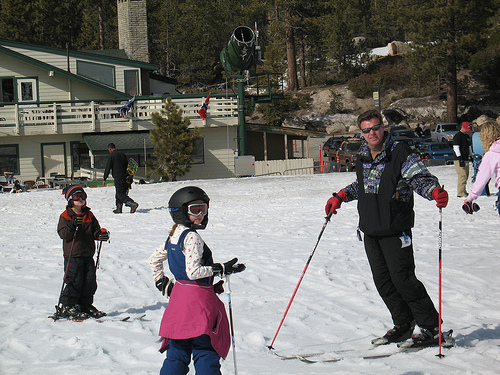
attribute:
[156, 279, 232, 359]
jacket — pink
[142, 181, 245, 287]
girl — young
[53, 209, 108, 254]
jacket — black, red, brown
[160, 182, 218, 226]
helmet — black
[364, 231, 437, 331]
pants — black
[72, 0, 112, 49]
tree — green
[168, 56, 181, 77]
branches — green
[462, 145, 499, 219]
sweater — pink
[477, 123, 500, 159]
woman — blonde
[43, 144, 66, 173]
door — white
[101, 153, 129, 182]
shirt — black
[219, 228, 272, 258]
snow — white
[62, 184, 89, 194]
hat — black, red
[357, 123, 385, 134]
sunglasses — dark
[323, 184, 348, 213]
glove — red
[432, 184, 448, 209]
glove — red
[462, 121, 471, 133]
cap — red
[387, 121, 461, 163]
cars — parked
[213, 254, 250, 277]
glove — black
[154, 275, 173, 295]
glove — black